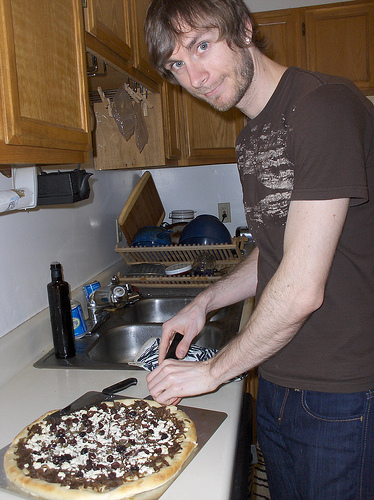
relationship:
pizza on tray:
[9, 398, 194, 495] [1, 390, 228, 500]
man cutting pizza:
[145, 1, 373, 453] [9, 398, 194, 495]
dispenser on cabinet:
[2, 166, 40, 216] [2, 1, 86, 165]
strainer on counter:
[115, 239, 243, 289] [1, 368, 73, 405]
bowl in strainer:
[177, 214, 232, 249] [115, 239, 243, 289]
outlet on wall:
[218, 201, 231, 223] [157, 168, 233, 203]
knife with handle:
[57, 376, 140, 412] [100, 374, 139, 398]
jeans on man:
[256, 381, 372, 500] [145, 1, 373, 453]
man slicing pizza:
[145, 1, 373, 453] [9, 398, 194, 495]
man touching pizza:
[145, 1, 373, 453] [9, 398, 194, 495]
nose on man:
[183, 55, 211, 91] [145, 1, 373, 453]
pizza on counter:
[9, 398, 194, 495] [1, 368, 73, 405]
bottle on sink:
[46, 259, 81, 358] [90, 287, 154, 368]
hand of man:
[147, 354, 217, 407] [145, 1, 373, 453]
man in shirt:
[145, 1, 373, 453] [234, 90, 374, 370]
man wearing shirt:
[145, 1, 373, 453] [234, 90, 374, 370]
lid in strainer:
[165, 261, 190, 276] [115, 239, 243, 289]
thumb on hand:
[173, 332, 191, 360] [147, 354, 217, 407]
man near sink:
[145, 1, 373, 453] [90, 287, 154, 368]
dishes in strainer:
[118, 170, 234, 283] [115, 239, 243, 289]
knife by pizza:
[57, 376, 140, 412] [9, 398, 194, 495]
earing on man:
[243, 35, 252, 46] [145, 1, 373, 453]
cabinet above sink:
[84, 0, 160, 90] [90, 287, 154, 368]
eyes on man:
[197, 39, 211, 55] [145, 1, 373, 453]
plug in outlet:
[219, 212, 227, 224] [218, 201, 231, 223]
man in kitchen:
[145, 1, 373, 453] [4, 2, 146, 499]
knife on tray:
[57, 376, 140, 412] [1, 390, 228, 500]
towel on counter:
[131, 333, 161, 372] [1, 368, 73, 405]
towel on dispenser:
[0, 183, 37, 214] [2, 166, 40, 216]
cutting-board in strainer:
[112, 168, 167, 245] [115, 239, 243, 289]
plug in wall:
[219, 212, 227, 224] [157, 168, 233, 203]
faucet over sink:
[92, 287, 129, 310] [90, 287, 154, 368]